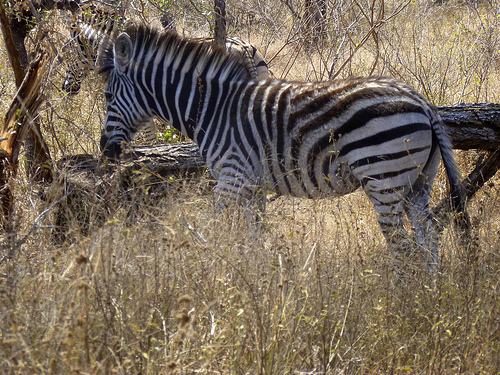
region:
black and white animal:
[33, 16, 452, 214]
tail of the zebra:
[410, 110, 477, 201]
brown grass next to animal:
[73, 223, 196, 314]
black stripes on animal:
[227, 81, 343, 137]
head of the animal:
[77, 25, 157, 150]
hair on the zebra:
[145, 21, 250, 78]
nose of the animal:
[81, 112, 127, 164]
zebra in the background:
[38, 11, 105, 76]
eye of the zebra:
[96, 74, 121, 116]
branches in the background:
[277, 12, 403, 67]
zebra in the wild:
[73, 5, 448, 241]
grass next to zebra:
[101, 235, 186, 300]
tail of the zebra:
[430, 150, 480, 210]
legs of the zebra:
[360, 205, 445, 260]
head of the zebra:
[65, 35, 165, 145]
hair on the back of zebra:
[150, 30, 250, 80]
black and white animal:
[210, 85, 345, 165]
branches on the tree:
[40, 85, 95, 150]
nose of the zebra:
[88, 116, 129, 166]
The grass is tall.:
[61, 235, 266, 373]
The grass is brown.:
[77, 239, 256, 371]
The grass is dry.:
[98, 241, 243, 373]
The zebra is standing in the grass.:
[81, 20, 478, 295]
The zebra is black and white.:
[96, 17, 479, 294]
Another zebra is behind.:
[49, 5, 271, 103]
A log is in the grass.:
[30, 90, 499, 231]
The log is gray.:
[34, 88, 496, 216]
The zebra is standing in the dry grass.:
[81, 10, 472, 307]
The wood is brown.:
[1, 0, 82, 245]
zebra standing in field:
[58, 25, 458, 276]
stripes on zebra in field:
[334, 125, 421, 144]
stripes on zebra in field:
[248, 111, 272, 167]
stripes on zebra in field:
[242, 90, 253, 142]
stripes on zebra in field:
[189, 56, 201, 126]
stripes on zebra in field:
[156, 47, 162, 111]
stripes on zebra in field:
[134, 42, 143, 106]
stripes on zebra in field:
[165, 62, 176, 132]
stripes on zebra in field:
[353, 167, 408, 184]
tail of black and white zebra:
[421, 126, 467, 223]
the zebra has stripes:
[92, 22, 470, 292]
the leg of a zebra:
[355, 145, 406, 286]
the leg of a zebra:
[410, 180, 445, 270]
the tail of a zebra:
[430, 120, 475, 245]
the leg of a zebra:
[202, 163, 258, 264]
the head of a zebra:
[97, 25, 160, 160]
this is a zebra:
[95, 26, 470, 291]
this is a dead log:
[35, 86, 497, 222]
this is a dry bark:
[0, 20, 55, 188]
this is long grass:
[0, 201, 495, 373]